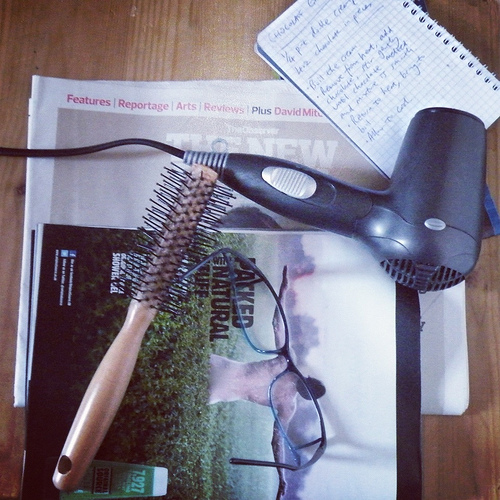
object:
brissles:
[110, 162, 238, 315]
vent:
[377, 253, 475, 296]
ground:
[435, 152, 448, 175]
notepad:
[254, 0, 500, 182]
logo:
[69, 250, 77, 259]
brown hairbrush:
[30, 160, 235, 493]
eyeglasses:
[164, 248, 328, 488]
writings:
[66, 93, 317, 118]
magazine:
[10, 72, 470, 417]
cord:
[2, 137, 178, 160]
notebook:
[12, 74, 474, 419]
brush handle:
[51, 302, 150, 491]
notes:
[275, 0, 425, 148]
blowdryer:
[178, 106, 487, 294]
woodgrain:
[438, 417, 486, 483]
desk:
[0, 0, 500, 500]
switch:
[260, 165, 317, 199]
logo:
[61, 249, 69, 257]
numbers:
[129, 467, 146, 495]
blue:
[213, 256, 291, 476]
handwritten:
[354, 101, 390, 143]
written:
[329, 65, 399, 147]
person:
[205, 264, 324, 500]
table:
[0, 0, 500, 500]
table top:
[54, 50, 107, 116]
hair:
[129, 171, 194, 298]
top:
[382, 108, 482, 239]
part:
[301, 235, 402, 498]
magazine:
[19, 221, 425, 498]